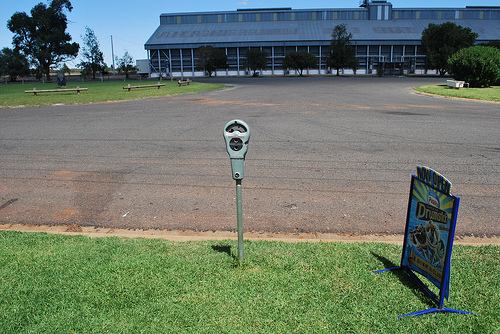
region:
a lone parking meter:
[223, 116, 250, 265]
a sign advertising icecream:
[376, 166, 463, 314]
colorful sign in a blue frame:
[377, 171, 468, 314]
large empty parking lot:
[162, 76, 468, 111]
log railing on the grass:
[29, 76, 195, 98]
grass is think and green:
[0, 233, 499, 330]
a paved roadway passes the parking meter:
[1, 108, 498, 234]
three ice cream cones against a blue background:
[408, 218, 449, 263]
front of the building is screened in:
[156, 41, 450, 73]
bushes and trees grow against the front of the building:
[193, 26, 499, 76]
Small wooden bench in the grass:
[27, 82, 87, 101]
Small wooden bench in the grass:
[109, 77, 169, 99]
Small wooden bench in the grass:
[171, 72, 196, 89]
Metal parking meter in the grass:
[218, 112, 255, 279]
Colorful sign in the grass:
[376, 151, 476, 330]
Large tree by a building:
[188, 37, 229, 78]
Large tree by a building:
[242, 47, 267, 77]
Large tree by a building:
[282, 46, 322, 86]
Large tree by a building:
[319, 19, 359, 91]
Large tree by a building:
[412, 10, 460, 87]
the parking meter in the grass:
[213, 108, 262, 273]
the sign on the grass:
[371, 161, 478, 321]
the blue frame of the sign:
[374, 163, 479, 322]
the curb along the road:
[0, 217, 180, 239]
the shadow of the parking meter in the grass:
[208, 238, 235, 263]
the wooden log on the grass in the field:
[16, 81, 96, 101]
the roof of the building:
[146, 8, 498, 40]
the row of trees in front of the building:
[196, 21, 357, 81]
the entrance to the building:
[376, 58, 406, 78]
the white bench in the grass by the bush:
[443, 75, 466, 90]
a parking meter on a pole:
[219, 74, 336, 332]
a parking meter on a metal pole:
[196, 94, 336, 291]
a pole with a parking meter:
[214, 114, 289, 261]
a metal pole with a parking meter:
[190, 97, 300, 270]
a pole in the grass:
[194, 94, 319, 333]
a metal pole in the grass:
[187, 118, 304, 270]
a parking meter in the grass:
[224, 124, 296, 253]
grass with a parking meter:
[193, 94, 314, 276]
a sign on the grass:
[339, 147, 467, 323]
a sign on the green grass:
[349, 147, 488, 320]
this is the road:
[132, 114, 192, 204]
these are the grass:
[120, 251, 212, 316]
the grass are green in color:
[130, 240, 226, 332]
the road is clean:
[283, 89, 380, 171]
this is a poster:
[369, 162, 459, 295]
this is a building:
[305, 3, 384, 60]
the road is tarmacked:
[278, 101, 378, 176]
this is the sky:
[105, 6, 141, 24]